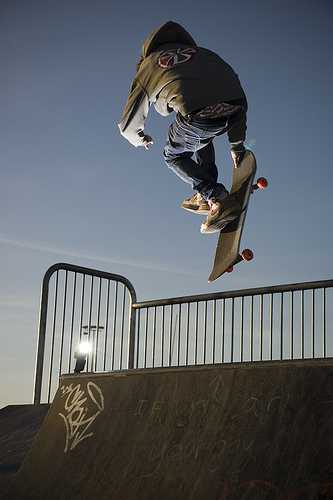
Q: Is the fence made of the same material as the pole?
A: Yes, both the fence and the pole are made of metal.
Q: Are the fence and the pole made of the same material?
A: Yes, both the fence and the pole are made of metal.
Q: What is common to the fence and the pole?
A: The material, both the fence and the pole are metallic.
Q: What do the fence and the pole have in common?
A: The material, both the fence and the pole are metallic.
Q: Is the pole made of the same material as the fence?
A: Yes, both the pole and the fence are made of metal.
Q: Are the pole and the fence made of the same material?
A: Yes, both the pole and the fence are made of metal.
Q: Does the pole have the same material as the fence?
A: Yes, both the pole and the fence are made of metal.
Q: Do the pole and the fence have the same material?
A: Yes, both the pole and the fence are made of metal.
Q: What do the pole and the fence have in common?
A: The material, both the pole and the fence are metallic.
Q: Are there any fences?
A: Yes, there is a fence.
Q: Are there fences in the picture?
A: Yes, there is a fence.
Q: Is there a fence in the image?
A: Yes, there is a fence.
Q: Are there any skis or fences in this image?
A: Yes, there is a fence.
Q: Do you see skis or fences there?
A: Yes, there is a fence.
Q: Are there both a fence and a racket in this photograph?
A: No, there is a fence but no rackets.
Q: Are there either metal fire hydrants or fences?
A: Yes, there is a metal fence.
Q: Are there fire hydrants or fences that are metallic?
A: Yes, the fence is metallic.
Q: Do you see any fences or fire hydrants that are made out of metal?
A: Yes, the fence is made of metal.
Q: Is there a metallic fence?
A: Yes, there is a metal fence.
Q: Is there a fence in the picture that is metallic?
A: Yes, there is a fence that is metallic.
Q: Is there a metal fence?
A: Yes, there is a fence that is made of metal.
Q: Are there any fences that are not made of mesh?
A: Yes, there is a fence that is made of metal.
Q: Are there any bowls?
A: No, there are no bowls.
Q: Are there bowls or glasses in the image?
A: No, there are no bowls or glasses.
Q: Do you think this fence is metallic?
A: Yes, the fence is metallic.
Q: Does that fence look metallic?
A: Yes, the fence is metallic.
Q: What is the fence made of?
A: The fence is made of metal.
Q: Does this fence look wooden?
A: No, the fence is metallic.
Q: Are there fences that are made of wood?
A: No, there is a fence but it is made of metal.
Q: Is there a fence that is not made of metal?
A: No, there is a fence but it is made of metal.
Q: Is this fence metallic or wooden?
A: The fence is metallic.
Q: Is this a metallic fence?
A: Yes, this is a metallic fence.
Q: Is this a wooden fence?
A: No, this is a metallic fence.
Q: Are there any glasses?
A: No, there are no glasses.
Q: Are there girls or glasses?
A: No, there are no glasses or girls.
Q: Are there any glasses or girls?
A: No, there are no glasses or girls.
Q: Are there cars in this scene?
A: No, there are no cars.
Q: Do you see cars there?
A: No, there are no cars.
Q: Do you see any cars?
A: No, there are no cars.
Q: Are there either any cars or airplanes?
A: No, there are no cars or airplanes.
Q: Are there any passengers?
A: No, there are no passengers.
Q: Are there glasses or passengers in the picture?
A: No, there are no passengers or glasses.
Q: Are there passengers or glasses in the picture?
A: No, there are no passengers or glasses.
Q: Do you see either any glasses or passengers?
A: No, there are no passengers or glasses.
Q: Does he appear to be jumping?
A: Yes, the man is jumping.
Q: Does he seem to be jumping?
A: Yes, the man is jumping.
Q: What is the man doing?
A: The man is jumping.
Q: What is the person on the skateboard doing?
A: The man is jumping.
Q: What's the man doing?
A: The man is jumping.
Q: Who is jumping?
A: The man is jumping.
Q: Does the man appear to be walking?
A: No, the man is jumping.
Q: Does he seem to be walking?
A: No, the man is jumping.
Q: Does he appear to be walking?
A: No, the man is jumping.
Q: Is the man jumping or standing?
A: The man is jumping.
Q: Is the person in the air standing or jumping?
A: The man is jumping.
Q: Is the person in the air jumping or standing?
A: The man is jumping.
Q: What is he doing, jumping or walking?
A: The man is jumping.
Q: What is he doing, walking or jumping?
A: The man is jumping.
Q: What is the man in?
A: The man is in the air.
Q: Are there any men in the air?
A: Yes, there is a man in the air.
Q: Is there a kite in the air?
A: No, there is a man in the air.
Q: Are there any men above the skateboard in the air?
A: Yes, there is a man above the skateboard.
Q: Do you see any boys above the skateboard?
A: No, there is a man above the skateboard.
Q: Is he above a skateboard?
A: Yes, the man is above a skateboard.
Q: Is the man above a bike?
A: No, the man is above a skateboard.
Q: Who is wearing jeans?
A: The man is wearing jeans.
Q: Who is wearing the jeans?
A: The man is wearing jeans.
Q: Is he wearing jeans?
A: Yes, the man is wearing jeans.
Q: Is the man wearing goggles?
A: No, the man is wearing jeans.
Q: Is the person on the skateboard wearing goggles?
A: No, the man is wearing jeans.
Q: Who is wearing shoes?
A: The man is wearing shoes.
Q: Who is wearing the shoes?
A: The man is wearing shoes.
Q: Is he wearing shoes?
A: Yes, the man is wearing shoes.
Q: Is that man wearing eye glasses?
A: No, the man is wearing shoes.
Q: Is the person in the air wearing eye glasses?
A: No, the man is wearing shoes.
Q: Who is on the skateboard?
A: The man is on the skateboard.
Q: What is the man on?
A: The man is on the skateboard.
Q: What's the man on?
A: The man is on the skateboard.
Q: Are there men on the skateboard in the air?
A: Yes, there is a man on the skateboard.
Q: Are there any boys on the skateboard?
A: No, there is a man on the skateboard.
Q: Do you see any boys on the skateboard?
A: No, there is a man on the skateboard.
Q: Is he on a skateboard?
A: Yes, the man is on a skateboard.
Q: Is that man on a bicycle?
A: No, the man is on a skateboard.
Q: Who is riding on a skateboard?
A: The man is riding on a skateboard.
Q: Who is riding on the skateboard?
A: The man is riding on a skateboard.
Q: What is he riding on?
A: The man is riding on a skateboard.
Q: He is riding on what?
A: The man is riding on a skateboard.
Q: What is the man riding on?
A: The man is riding on a skateboard.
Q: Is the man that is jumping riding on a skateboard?
A: Yes, the man is riding on a skateboard.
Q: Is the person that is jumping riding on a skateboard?
A: Yes, the man is riding on a skateboard.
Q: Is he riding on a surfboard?
A: No, the man is riding on a skateboard.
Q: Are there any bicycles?
A: No, there are no bicycles.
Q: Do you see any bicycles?
A: No, there are no bicycles.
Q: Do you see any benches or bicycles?
A: No, there are no bicycles or benches.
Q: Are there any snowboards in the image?
A: No, there are no snowboards.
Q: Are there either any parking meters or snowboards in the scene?
A: No, there are no snowboards or parking meters.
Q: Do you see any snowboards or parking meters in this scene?
A: No, there are no snowboards or parking meters.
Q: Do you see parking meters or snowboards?
A: No, there are no snowboards or parking meters.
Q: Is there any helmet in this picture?
A: No, there are no helmets.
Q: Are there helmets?
A: No, there are no helmets.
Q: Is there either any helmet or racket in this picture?
A: No, there are no helmets or rackets.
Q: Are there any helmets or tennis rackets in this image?
A: No, there are no helmets or tennis rackets.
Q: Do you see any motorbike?
A: No, there are no motorcycles.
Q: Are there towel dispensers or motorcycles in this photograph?
A: No, there are no motorcycles or towel dispensers.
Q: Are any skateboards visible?
A: Yes, there is a skateboard.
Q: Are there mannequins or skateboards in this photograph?
A: Yes, there is a skateboard.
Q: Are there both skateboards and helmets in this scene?
A: No, there is a skateboard but no helmets.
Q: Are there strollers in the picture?
A: No, there are no strollers.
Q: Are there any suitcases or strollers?
A: No, there are no strollers or suitcases.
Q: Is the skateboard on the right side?
A: Yes, the skateboard is on the right of the image.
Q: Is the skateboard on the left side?
A: No, the skateboard is on the right of the image.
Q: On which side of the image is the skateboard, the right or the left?
A: The skateboard is on the right of the image.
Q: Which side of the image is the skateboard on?
A: The skateboard is on the right of the image.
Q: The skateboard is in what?
A: The skateboard is in the air.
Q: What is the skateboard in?
A: The skateboard is in the air.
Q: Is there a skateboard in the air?
A: Yes, there is a skateboard in the air.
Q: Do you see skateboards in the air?
A: Yes, there is a skateboard in the air.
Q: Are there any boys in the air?
A: No, there is a skateboard in the air.